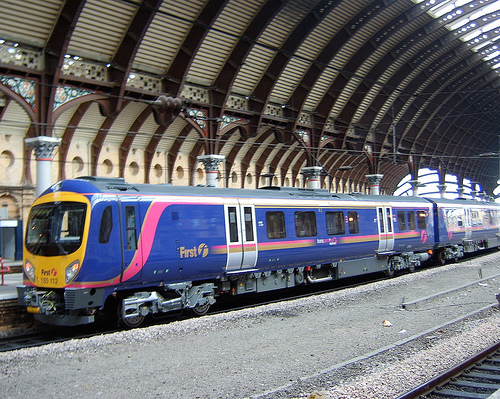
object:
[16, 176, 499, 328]
train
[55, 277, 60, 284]
number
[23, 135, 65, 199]
column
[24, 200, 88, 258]
windshield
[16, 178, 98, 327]
front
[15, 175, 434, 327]
engine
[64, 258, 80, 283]
headlight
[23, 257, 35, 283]
headlight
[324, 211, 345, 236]
window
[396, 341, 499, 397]
tracks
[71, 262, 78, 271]
light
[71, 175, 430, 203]
roof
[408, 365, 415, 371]
stones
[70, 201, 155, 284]
stripe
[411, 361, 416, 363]
gravel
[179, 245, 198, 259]
words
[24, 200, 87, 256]
window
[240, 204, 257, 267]
doors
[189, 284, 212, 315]
wheels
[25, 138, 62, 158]
decoration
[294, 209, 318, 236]
window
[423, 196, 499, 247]
car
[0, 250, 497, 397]
pavement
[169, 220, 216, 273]
logo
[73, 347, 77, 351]
gravel